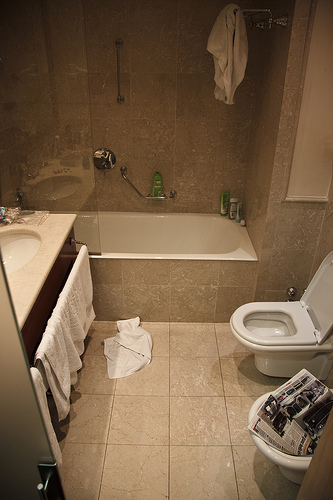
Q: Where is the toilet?
A: Across from the sink.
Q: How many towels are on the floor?
A: One.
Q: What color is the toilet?
A: White.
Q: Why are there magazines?
A: Too look at.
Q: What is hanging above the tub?
A: Towel.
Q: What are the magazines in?
A: A bucket.